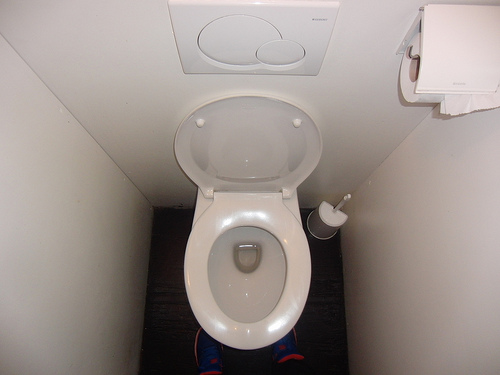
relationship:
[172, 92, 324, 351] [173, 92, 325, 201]
toilet has lid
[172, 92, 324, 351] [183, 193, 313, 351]
toilet has seat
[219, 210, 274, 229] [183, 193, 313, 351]
reflection on seat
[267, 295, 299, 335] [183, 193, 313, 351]
reflection on seat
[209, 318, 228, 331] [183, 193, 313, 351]
reflection on seat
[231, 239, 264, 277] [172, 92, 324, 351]
water in toilet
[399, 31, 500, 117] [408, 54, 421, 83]
toilet paper on roll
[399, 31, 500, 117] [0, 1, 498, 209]
toilet paper on wall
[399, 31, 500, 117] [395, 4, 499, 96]
toilet paper has cover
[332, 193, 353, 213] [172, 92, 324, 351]
toilet brush for toilet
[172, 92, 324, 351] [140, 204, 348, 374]
toilet on floor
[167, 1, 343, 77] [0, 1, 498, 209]
panel on wall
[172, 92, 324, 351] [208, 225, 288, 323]
toilet has bowl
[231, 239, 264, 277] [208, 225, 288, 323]
water in bowl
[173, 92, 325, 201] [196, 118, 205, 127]
lid has stopper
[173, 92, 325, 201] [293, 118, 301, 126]
lid has stopper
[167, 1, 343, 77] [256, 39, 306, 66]
panel has button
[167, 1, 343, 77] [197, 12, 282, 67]
panel has button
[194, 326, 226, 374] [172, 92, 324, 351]
shoe in front of toilet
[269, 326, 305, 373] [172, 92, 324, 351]
shoe in front of toilet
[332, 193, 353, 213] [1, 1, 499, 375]
toilet brush in scene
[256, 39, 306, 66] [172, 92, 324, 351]
button above toilet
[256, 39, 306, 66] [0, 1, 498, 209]
button on wall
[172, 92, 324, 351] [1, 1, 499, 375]
toilet in scene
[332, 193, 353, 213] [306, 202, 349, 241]
toilet brush in container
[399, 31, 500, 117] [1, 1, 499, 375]
toilet paper in scene